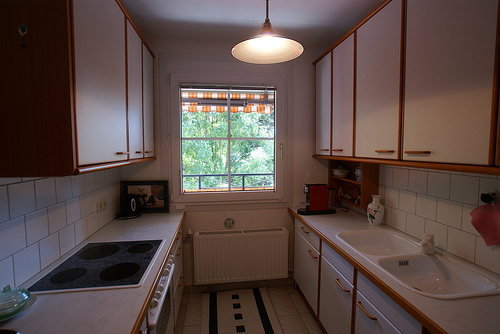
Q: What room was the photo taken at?
A: It was taken at the kitchen.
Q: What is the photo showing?
A: It is showing a kitchen.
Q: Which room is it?
A: It is a kitchen.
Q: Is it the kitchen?
A: Yes, it is the kitchen.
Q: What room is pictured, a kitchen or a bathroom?
A: It is a kitchen.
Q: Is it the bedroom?
A: No, it is the kitchen.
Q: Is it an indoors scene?
A: Yes, it is indoors.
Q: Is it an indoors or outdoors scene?
A: It is indoors.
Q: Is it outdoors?
A: No, it is indoors.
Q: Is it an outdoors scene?
A: No, it is indoors.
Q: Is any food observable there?
A: No, there is no food.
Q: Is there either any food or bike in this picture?
A: No, there are no food or bikes.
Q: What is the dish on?
A: The dish is on the counter.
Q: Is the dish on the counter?
A: Yes, the dish is on the counter.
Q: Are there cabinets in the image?
A: Yes, there is a cabinet.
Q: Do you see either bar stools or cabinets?
A: Yes, there is a cabinet.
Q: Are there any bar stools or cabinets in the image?
A: Yes, there is a cabinet.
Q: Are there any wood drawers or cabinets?
A: Yes, there is a wood cabinet.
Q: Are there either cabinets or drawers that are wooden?
A: Yes, the cabinet is wooden.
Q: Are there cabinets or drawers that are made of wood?
A: Yes, the cabinet is made of wood.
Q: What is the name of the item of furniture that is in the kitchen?
A: The piece of furniture is a cabinet.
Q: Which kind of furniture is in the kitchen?
A: The piece of furniture is a cabinet.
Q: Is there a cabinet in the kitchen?
A: Yes, there is a cabinet in the kitchen.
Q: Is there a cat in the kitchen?
A: No, there is a cabinet in the kitchen.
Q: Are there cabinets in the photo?
A: Yes, there is a cabinet.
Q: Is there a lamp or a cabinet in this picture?
A: Yes, there is a cabinet.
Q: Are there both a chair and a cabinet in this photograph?
A: No, there is a cabinet but no chairs.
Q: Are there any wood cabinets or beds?
A: Yes, there is a wood cabinet.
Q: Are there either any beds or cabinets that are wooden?
A: Yes, the cabinet is wooden.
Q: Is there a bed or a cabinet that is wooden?
A: Yes, the cabinet is wooden.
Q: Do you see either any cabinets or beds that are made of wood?
A: Yes, the cabinet is made of wood.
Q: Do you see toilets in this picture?
A: No, there are no toilets.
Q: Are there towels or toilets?
A: No, there are no toilets or towels.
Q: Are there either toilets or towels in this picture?
A: No, there are no toilets or towels.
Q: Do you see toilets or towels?
A: No, there are no toilets or towels.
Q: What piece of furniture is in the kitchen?
A: The piece of furniture is a cabinet.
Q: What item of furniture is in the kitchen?
A: The piece of furniture is a cabinet.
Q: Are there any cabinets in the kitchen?
A: Yes, there is a cabinet in the kitchen.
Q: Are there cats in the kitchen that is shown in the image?
A: No, there is a cabinet in the kitchen.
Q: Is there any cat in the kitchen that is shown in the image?
A: No, there is a cabinet in the kitchen.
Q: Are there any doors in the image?
A: Yes, there is a door.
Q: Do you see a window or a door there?
A: Yes, there is a door.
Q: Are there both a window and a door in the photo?
A: Yes, there are both a door and a window.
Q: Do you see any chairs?
A: No, there are no chairs.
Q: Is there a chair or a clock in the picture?
A: No, there are no chairs or clocks.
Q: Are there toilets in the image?
A: No, there are no toilets.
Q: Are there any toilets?
A: No, there are no toilets.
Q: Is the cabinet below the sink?
A: No, the sink is below the cabinet.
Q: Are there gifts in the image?
A: No, there are no gifts.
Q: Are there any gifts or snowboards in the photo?
A: No, there are no gifts or snowboards.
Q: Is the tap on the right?
A: Yes, the tap is on the right of the image.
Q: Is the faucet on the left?
A: No, the faucet is on the right of the image.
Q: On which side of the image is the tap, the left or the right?
A: The tap is on the right of the image.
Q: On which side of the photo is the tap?
A: The tap is on the right of the image.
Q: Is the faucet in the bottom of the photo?
A: Yes, the faucet is in the bottom of the image.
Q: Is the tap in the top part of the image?
A: No, the tap is in the bottom of the image.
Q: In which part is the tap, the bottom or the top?
A: The tap is in the bottom of the image.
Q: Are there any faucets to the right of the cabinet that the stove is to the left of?
A: Yes, there is a faucet to the right of the cabinet.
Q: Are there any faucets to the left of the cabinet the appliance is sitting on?
A: No, the faucet is to the right of the cabinet.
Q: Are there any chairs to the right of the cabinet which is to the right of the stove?
A: No, there is a faucet to the right of the cabinet.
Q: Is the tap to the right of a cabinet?
A: Yes, the tap is to the right of a cabinet.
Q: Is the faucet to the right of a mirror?
A: No, the faucet is to the right of a cabinet.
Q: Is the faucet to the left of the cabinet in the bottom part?
A: No, the faucet is to the right of the cabinet.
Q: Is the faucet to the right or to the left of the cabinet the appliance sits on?
A: The faucet is to the right of the cabinet.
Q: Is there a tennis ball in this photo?
A: No, there are no tennis balls.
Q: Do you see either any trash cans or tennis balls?
A: No, there are no tennis balls or trash cans.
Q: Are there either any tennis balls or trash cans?
A: No, there are no tennis balls or trash cans.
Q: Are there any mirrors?
A: No, there are no mirrors.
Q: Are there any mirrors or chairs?
A: No, there are no mirrors or chairs.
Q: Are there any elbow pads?
A: No, there are no elbow pads.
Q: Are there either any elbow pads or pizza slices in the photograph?
A: No, there are no elbow pads or pizza slices.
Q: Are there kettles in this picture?
A: Yes, there is a kettle.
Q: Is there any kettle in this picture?
A: Yes, there is a kettle.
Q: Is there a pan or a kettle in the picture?
A: Yes, there is a kettle.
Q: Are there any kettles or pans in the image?
A: Yes, there is a kettle.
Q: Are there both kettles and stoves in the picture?
A: Yes, there are both a kettle and a stove.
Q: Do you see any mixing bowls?
A: No, there are no mixing bowls.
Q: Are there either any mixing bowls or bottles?
A: No, there are no mixing bowls or bottles.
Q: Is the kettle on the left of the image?
A: Yes, the kettle is on the left of the image.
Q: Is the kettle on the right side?
A: No, the kettle is on the left of the image.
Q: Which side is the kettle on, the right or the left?
A: The kettle is on the left of the image.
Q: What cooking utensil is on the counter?
A: The cooking utensil is a kettle.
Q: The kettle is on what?
A: The kettle is on the counter.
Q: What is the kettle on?
A: The kettle is on the counter.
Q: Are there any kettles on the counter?
A: Yes, there is a kettle on the counter.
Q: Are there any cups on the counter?
A: No, there is a kettle on the counter.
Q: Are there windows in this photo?
A: Yes, there is a window.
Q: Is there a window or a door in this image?
A: Yes, there is a window.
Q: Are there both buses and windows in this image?
A: No, there is a window but no buses.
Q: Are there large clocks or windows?
A: Yes, there is a large window.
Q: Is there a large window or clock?
A: Yes, there is a large window.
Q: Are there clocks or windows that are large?
A: Yes, the window is large.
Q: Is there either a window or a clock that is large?
A: Yes, the window is large.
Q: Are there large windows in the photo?
A: Yes, there is a large window.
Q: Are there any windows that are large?
A: Yes, there is a window that is large.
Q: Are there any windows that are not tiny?
A: Yes, there is a large window.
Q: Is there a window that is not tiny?
A: Yes, there is a large window.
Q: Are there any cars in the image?
A: No, there are no cars.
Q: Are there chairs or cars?
A: No, there are no cars or chairs.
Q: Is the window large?
A: Yes, the window is large.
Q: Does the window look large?
A: Yes, the window is large.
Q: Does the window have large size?
A: Yes, the window is large.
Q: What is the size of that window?
A: The window is large.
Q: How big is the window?
A: The window is large.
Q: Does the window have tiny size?
A: No, the window is large.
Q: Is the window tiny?
A: No, the window is large.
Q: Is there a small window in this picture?
A: No, there is a window but it is large.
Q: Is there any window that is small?
A: No, there is a window but it is large.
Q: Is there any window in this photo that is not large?
A: No, there is a window but it is large.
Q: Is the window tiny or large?
A: The window is large.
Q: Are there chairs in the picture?
A: No, there are no chairs.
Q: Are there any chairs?
A: No, there are no chairs.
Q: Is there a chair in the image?
A: No, there are no chairs.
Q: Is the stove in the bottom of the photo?
A: Yes, the stove is in the bottom of the image.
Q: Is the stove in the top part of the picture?
A: No, the stove is in the bottom of the image.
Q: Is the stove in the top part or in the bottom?
A: The stove is in the bottom of the image.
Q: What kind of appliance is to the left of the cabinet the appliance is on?
A: The appliance is a stove.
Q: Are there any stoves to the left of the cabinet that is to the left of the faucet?
A: Yes, there is a stove to the left of the cabinet.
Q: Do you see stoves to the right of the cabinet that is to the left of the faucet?
A: No, the stove is to the left of the cabinet.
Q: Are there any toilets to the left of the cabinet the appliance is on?
A: No, there is a stove to the left of the cabinet.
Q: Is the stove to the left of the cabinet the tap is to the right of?
A: Yes, the stove is to the left of the cabinet.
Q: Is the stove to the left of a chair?
A: No, the stove is to the left of the cabinet.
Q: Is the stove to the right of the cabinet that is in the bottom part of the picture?
A: No, the stove is to the left of the cabinet.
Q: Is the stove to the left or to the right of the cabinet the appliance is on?
A: The stove is to the left of the cabinet.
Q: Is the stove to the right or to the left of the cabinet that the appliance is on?
A: The stove is to the left of the cabinet.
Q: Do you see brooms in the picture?
A: No, there are no brooms.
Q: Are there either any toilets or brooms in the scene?
A: No, there are no brooms or toilets.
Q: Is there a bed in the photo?
A: No, there are no beds.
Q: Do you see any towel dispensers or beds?
A: No, there are no beds or towel dispensers.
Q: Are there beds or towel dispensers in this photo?
A: No, there are no beds or towel dispensers.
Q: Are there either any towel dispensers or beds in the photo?
A: No, there are no beds or towel dispensers.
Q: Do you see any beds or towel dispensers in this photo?
A: No, there are no beds or towel dispensers.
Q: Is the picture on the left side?
A: Yes, the picture is on the left of the image.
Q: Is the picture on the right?
A: No, the picture is on the left of the image.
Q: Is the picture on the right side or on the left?
A: The picture is on the left of the image.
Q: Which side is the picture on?
A: The picture is on the left of the image.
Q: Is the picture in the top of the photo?
A: Yes, the picture is in the top of the image.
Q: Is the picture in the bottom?
A: No, the picture is in the top of the image.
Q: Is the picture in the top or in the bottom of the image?
A: The picture is in the top of the image.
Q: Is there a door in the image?
A: Yes, there is a door.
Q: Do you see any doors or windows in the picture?
A: Yes, there is a door.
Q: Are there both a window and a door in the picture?
A: Yes, there are both a door and a window.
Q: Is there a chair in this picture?
A: No, there are no chairs.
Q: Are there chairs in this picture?
A: No, there are no chairs.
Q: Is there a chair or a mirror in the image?
A: No, there are no chairs or mirrors.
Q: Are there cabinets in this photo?
A: Yes, there is a cabinet.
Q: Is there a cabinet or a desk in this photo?
A: Yes, there is a cabinet.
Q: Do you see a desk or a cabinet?
A: Yes, there is a cabinet.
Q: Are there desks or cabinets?
A: Yes, there is a cabinet.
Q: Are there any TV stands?
A: No, there are no TV stands.